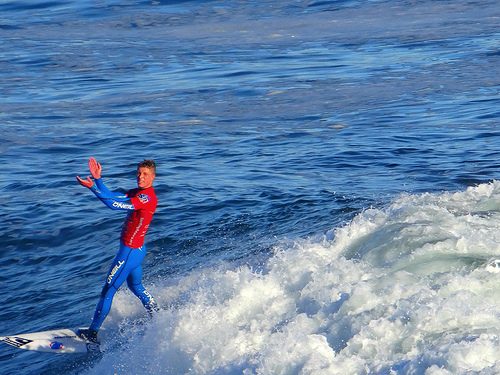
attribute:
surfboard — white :
[0, 320, 115, 356]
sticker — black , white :
[46, 339, 65, 349]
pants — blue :
[74, 244, 159, 338]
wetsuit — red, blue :
[85, 175, 160, 336]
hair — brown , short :
[134, 159, 157, 191]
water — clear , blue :
[3, 6, 498, 369]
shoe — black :
[73, 321, 102, 345]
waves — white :
[139, 200, 492, 371]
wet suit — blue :
[89, 177, 157, 332]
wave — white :
[97, 180, 497, 371]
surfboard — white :
[0, 326, 119, 355]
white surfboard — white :
[0, 322, 136, 355]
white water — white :
[279, 176, 411, 299]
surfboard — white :
[2, 318, 147, 367]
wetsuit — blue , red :
[72, 180, 168, 330]